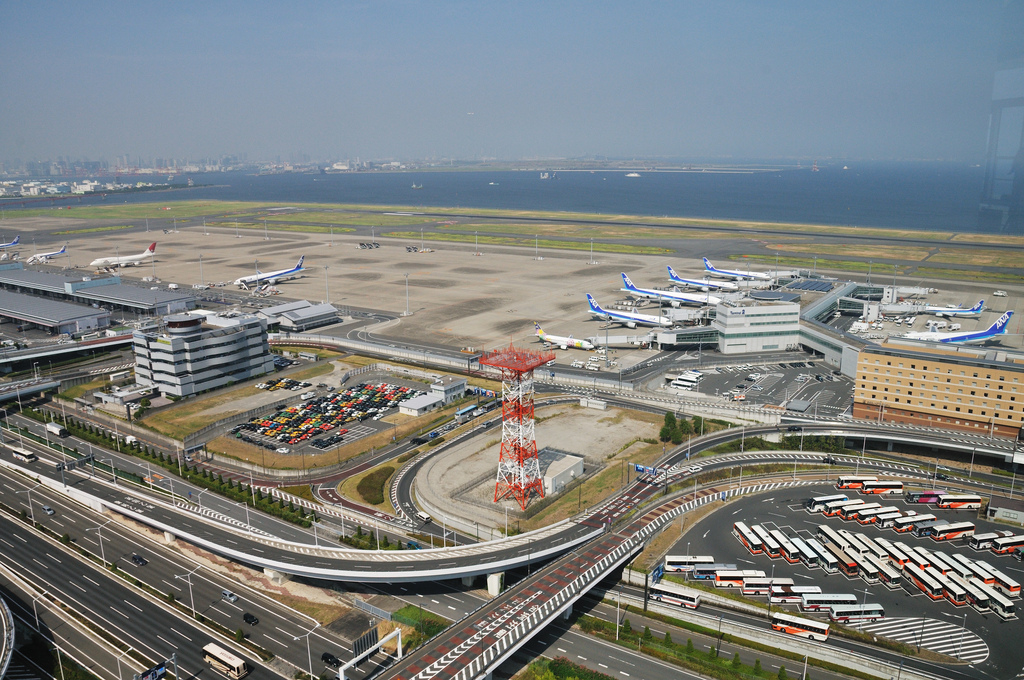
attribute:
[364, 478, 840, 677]
street — gray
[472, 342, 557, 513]
tower — red, white, metal, orange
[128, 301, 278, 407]
building — white, large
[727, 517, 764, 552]
bus — white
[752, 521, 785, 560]
bus — white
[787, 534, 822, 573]
bus — white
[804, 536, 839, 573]
bus — white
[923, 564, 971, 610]
bus — white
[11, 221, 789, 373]
tarmac — large, gray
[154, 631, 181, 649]
line — white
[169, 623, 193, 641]
line — white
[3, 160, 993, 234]
water — blue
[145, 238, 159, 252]
tail — red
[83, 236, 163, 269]
airplane — white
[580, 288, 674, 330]
airplane — white, blue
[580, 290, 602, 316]
tail — blue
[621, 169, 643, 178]
boat — white